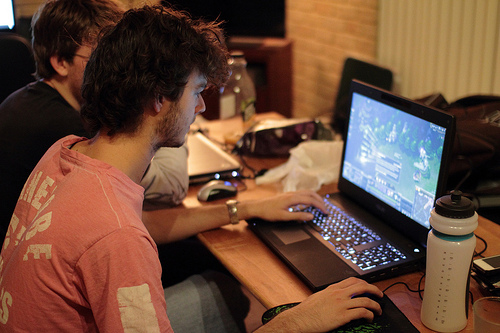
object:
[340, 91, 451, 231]
screen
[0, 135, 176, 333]
shirt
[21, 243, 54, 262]
letters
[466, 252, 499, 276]
phone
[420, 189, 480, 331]
bottle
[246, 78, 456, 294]
laptop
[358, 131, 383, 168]
ground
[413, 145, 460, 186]
ground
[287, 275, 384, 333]
hand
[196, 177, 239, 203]
computer mouse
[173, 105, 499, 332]
table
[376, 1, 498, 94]
blinds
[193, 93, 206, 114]
nose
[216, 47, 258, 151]
bottle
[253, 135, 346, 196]
paper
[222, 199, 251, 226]
wrist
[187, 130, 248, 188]
laptop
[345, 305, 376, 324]
finger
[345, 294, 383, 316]
finger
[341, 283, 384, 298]
finger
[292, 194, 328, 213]
finger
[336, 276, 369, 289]
finger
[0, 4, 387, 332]
man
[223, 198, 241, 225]
watch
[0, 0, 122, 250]
man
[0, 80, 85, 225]
black shirt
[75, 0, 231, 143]
hair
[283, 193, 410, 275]
computer keyboard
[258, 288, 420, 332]
mouse pad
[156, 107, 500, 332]
desk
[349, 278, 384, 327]
mouse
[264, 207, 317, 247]
trackpad